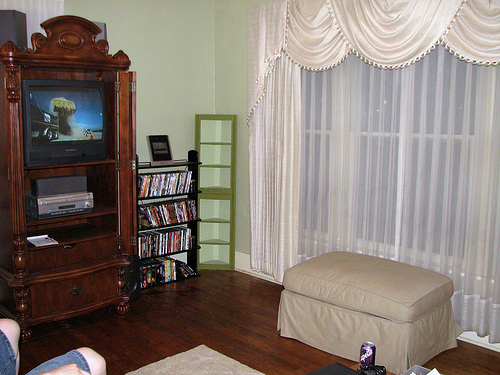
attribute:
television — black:
[18, 74, 113, 164]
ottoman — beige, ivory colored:
[274, 244, 460, 374]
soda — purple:
[358, 340, 380, 367]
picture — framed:
[145, 131, 177, 167]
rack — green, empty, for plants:
[192, 109, 244, 273]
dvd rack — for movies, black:
[137, 155, 204, 294]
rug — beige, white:
[120, 342, 283, 374]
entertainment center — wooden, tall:
[3, 13, 152, 341]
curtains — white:
[295, 69, 484, 273]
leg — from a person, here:
[0, 312, 24, 371]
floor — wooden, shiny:
[192, 284, 250, 337]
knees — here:
[1, 313, 117, 372]